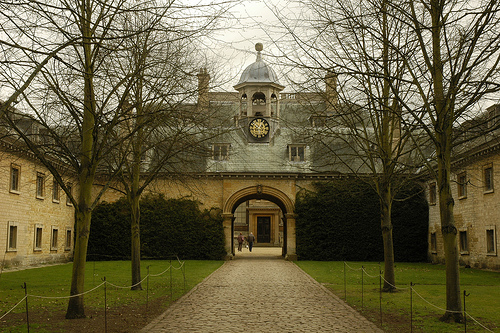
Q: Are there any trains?
A: No, there are no trains.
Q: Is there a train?
A: No, there are no trains.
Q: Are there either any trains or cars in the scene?
A: No, there are no trains or cars.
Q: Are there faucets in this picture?
A: No, there are no faucets.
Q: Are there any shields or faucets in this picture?
A: No, there are no faucets or shields.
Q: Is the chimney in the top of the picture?
A: Yes, the chimney is in the top of the image.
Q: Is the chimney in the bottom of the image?
A: No, the chimney is in the top of the image.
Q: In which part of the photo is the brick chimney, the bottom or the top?
A: The chimney is in the top of the image.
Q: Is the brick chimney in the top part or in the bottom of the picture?
A: The chimney is in the top of the image.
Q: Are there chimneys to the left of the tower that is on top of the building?
A: Yes, there is a chimney to the left of the tower.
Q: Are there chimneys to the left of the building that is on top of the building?
A: Yes, there is a chimney to the left of the tower.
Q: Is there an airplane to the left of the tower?
A: No, there is a chimney to the left of the tower.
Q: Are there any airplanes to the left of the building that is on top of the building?
A: No, there is a chimney to the left of the tower.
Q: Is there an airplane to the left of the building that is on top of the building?
A: No, there is a chimney to the left of the tower.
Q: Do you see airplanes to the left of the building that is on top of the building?
A: No, there is a chimney to the left of the tower.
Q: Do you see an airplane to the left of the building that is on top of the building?
A: No, there is a chimney to the left of the tower.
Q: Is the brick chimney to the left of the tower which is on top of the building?
A: Yes, the chimney is to the left of the tower.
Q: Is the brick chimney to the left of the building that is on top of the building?
A: Yes, the chimney is to the left of the tower.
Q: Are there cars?
A: No, there are no cars.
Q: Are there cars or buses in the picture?
A: No, there are no cars or buses.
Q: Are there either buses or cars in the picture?
A: No, there are no cars or buses.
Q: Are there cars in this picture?
A: No, there are no cars.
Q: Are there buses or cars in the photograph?
A: No, there are no cars or buses.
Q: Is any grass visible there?
A: Yes, there is grass.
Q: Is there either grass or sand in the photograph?
A: Yes, there is grass.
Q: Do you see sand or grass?
A: Yes, there is grass.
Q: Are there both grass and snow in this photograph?
A: No, there is grass but no snow.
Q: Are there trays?
A: No, there are no trays.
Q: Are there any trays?
A: No, there are no trays.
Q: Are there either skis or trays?
A: No, there are no trays or skis.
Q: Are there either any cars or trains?
A: No, there are no cars or trains.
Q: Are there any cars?
A: No, there are no cars.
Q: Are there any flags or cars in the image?
A: No, there are no cars or flags.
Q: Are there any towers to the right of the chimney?
A: Yes, there is a tower to the right of the chimney.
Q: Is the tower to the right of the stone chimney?
A: Yes, the tower is to the right of the chimney.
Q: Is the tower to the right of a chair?
A: No, the tower is to the right of the chimney.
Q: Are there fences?
A: Yes, there is a fence.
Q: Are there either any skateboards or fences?
A: Yes, there is a fence.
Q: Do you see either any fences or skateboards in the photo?
A: Yes, there is a fence.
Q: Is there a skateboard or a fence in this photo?
A: Yes, there is a fence.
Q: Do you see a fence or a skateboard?
A: Yes, there is a fence.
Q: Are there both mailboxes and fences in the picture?
A: No, there is a fence but no mailboxes.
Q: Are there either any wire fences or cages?
A: Yes, there is a wire fence.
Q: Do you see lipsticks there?
A: No, there are no lipsticks.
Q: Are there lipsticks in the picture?
A: No, there are no lipsticks.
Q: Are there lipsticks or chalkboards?
A: No, there are no lipsticks or chalkboards.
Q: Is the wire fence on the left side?
A: Yes, the fence is on the left of the image.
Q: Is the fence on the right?
A: No, the fence is on the left of the image.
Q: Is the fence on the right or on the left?
A: The fence is on the left of the image.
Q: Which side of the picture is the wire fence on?
A: The fence is on the left of the image.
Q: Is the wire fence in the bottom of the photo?
A: Yes, the fence is in the bottom of the image.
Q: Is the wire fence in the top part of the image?
A: No, the fence is in the bottom of the image.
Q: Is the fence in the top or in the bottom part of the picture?
A: The fence is in the bottom of the image.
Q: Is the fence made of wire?
A: Yes, the fence is made of wire.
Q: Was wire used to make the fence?
A: Yes, the fence is made of wire.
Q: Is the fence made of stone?
A: No, the fence is made of wire.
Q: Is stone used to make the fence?
A: No, the fence is made of wire.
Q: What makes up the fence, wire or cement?
A: The fence is made of wire.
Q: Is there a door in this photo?
A: Yes, there is a door.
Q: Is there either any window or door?
A: Yes, there is a door.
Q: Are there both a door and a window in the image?
A: Yes, there are both a door and a window.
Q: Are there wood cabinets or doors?
A: Yes, there is a wood door.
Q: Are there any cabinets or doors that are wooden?
A: Yes, the door is wooden.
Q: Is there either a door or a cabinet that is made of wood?
A: Yes, the door is made of wood.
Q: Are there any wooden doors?
A: Yes, there is a wood door.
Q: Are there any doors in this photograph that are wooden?
A: Yes, there is a door that is wooden.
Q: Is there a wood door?
A: Yes, there is a door that is made of wood.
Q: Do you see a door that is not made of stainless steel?
A: Yes, there is a door that is made of wood.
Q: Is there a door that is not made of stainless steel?
A: Yes, there is a door that is made of wood.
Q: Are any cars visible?
A: No, there are no cars.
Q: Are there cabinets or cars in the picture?
A: No, there are no cars or cabinets.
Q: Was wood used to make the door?
A: Yes, the door is made of wood.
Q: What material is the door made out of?
A: The door is made of wood.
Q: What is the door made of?
A: The door is made of wood.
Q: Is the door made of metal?
A: No, the door is made of wood.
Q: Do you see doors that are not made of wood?
A: No, there is a door but it is made of wood.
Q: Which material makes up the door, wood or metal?
A: The door is made of wood.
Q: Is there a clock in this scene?
A: Yes, there is a clock.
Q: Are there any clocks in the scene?
A: Yes, there is a clock.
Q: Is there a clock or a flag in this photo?
A: Yes, there is a clock.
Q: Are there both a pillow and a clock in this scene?
A: No, there is a clock but no pillows.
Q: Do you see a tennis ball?
A: No, there are no tennis balls.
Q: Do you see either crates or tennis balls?
A: No, there are no tennis balls or crates.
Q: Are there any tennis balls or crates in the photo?
A: No, there are no tennis balls or crates.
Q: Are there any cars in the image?
A: No, there are no cars.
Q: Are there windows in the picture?
A: Yes, there is a window.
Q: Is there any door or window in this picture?
A: Yes, there is a window.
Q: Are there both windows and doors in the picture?
A: Yes, there are both a window and doors.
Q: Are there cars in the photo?
A: No, there are no cars.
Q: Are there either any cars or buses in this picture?
A: No, there are no cars or buses.